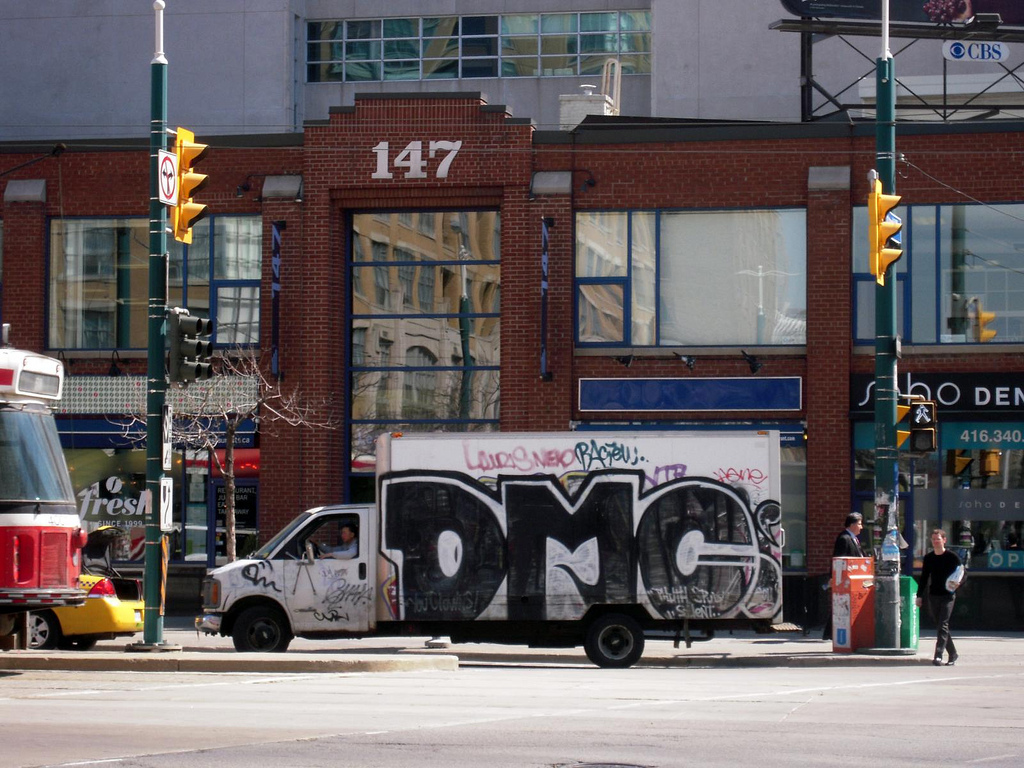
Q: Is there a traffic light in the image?
A: Yes, there is a traffic light.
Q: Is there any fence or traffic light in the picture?
A: Yes, there is a traffic light.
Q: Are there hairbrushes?
A: No, there are no hairbrushes.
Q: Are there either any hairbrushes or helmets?
A: No, there are no hairbrushes or helmets.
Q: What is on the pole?
A: The signal light is on the pole.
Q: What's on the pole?
A: The signal light is on the pole.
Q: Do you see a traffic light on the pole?
A: Yes, there is a traffic light on the pole.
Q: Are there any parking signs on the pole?
A: No, there is a traffic light on the pole.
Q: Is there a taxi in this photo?
A: Yes, there is a taxi.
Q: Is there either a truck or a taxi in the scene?
A: Yes, there is a taxi.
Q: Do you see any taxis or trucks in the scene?
A: Yes, there is a taxi.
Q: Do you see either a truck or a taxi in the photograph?
A: Yes, there is a taxi.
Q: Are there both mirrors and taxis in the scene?
A: No, there is a taxi but no mirrors.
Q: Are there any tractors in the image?
A: No, there are no tractors.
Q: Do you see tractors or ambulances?
A: No, there are no tractors or ambulances.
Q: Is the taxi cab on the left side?
A: Yes, the taxi cab is on the left of the image.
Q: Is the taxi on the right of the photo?
A: No, the taxi is on the left of the image.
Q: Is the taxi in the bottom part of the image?
A: Yes, the taxi is in the bottom of the image.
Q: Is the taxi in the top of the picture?
A: No, the taxi is in the bottom of the image.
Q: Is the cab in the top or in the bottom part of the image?
A: The cab is in the bottom of the image.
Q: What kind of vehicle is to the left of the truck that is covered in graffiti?
A: The vehicle is a taxi.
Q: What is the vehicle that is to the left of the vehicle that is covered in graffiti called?
A: The vehicle is a taxi.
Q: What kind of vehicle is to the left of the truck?
A: The vehicle is a taxi.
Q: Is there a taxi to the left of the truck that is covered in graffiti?
A: Yes, there is a taxi to the left of the truck.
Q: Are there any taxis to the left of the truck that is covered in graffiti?
A: Yes, there is a taxi to the left of the truck.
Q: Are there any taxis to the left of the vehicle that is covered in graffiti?
A: Yes, there is a taxi to the left of the truck.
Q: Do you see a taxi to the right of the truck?
A: No, the taxi is to the left of the truck.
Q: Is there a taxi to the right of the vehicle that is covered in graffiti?
A: No, the taxi is to the left of the truck.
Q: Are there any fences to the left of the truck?
A: No, there is a taxi to the left of the truck.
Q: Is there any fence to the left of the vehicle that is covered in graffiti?
A: No, there is a taxi to the left of the truck.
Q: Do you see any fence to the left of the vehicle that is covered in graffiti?
A: No, there is a taxi to the left of the truck.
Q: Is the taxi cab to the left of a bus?
A: No, the taxi cab is to the left of the truck.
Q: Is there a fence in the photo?
A: No, there are no fences.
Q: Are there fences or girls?
A: No, there are no fences or girls.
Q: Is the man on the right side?
A: Yes, the man is on the right of the image.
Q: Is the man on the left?
A: No, the man is on the right of the image.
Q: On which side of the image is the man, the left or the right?
A: The man is on the right of the image.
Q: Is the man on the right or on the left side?
A: The man is on the right of the image.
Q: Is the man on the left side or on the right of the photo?
A: The man is on the right of the image.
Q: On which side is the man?
A: The man is on the right of the image.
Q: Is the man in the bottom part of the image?
A: Yes, the man is in the bottom of the image.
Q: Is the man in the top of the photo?
A: No, the man is in the bottom of the image.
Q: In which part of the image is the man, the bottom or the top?
A: The man is in the bottom of the image.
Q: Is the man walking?
A: Yes, the man is walking.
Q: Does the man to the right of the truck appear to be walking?
A: Yes, the man is walking.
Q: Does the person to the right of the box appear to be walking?
A: Yes, the man is walking.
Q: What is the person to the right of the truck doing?
A: The man is walking.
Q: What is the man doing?
A: The man is walking.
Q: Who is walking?
A: The man is walking.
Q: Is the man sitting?
A: No, the man is walking.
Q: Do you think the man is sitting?
A: No, the man is walking.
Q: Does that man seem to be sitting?
A: No, the man is walking.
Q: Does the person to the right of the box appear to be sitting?
A: No, the man is walking.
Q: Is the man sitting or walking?
A: The man is walking.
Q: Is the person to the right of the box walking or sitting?
A: The man is walking.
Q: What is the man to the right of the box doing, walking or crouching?
A: The man is walking.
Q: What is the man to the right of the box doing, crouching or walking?
A: The man is walking.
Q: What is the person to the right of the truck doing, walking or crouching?
A: The man is walking.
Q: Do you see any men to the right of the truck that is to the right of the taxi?
A: Yes, there is a man to the right of the truck.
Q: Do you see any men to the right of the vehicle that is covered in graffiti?
A: Yes, there is a man to the right of the truck.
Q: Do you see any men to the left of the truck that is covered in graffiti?
A: No, the man is to the right of the truck.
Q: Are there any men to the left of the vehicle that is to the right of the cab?
A: No, the man is to the right of the truck.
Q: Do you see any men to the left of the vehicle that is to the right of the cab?
A: No, the man is to the right of the truck.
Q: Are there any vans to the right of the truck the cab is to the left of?
A: No, there is a man to the right of the truck.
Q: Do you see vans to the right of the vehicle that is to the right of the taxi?
A: No, there is a man to the right of the truck.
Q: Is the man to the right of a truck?
A: Yes, the man is to the right of a truck.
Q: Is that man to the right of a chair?
A: No, the man is to the right of a truck.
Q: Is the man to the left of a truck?
A: No, the man is to the right of a truck.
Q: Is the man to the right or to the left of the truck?
A: The man is to the right of the truck.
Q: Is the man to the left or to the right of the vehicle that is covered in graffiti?
A: The man is to the right of the truck.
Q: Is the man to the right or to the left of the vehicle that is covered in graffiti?
A: The man is to the right of the truck.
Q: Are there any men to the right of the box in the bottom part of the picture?
A: Yes, there is a man to the right of the box.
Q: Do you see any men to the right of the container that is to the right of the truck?
A: Yes, there is a man to the right of the box.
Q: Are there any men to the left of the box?
A: No, the man is to the right of the box.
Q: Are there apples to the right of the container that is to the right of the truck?
A: No, there is a man to the right of the box.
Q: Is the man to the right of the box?
A: Yes, the man is to the right of the box.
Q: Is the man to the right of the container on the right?
A: Yes, the man is to the right of the box.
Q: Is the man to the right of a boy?
A: No, the man is to the right of the box.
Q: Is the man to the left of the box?
A: No, the man is to the right of the box.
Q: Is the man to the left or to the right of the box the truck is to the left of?
A: The man is to the right of the box.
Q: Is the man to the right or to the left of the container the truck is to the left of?
A: The man is to the right of the box.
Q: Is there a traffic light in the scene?
A: Yes, there is a traffic light.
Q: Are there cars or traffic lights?
A: Yes, there is a traffic light.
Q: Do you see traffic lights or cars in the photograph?
A: Yes, there is a traffic light.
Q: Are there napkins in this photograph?
A: No, there are no napkins.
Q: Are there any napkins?
A: No, there are no napkins.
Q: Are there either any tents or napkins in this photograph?
A: No, there are no napkins or tents.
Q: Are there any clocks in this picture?
A: No, there are no clocks.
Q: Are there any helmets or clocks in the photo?
A: No, there are no clocks or helmets.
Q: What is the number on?
A: The number is on the building.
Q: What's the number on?
A: The number is on the building.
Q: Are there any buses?
A: No, there are no buses.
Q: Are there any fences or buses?
A: No, there are no buses or fences.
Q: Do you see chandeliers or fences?
A: No, there are no fences or chandeliers.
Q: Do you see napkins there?
A: No, there are no napkins.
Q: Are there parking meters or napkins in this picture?
A: No, there are no napkins or parking meters.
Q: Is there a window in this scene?
A: Yes, there is a window.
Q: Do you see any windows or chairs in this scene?
A: Yes, there is a window.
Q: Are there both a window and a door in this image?
A: No, there is a window but no doors.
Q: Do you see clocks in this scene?
A: No, there are no clocks.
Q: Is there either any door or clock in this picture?
A: No, there are no clocks or doors.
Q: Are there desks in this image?
A: No, there are no desks.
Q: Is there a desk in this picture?
A: No, there are no desks.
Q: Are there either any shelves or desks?
A: No, there are no desks or shelves.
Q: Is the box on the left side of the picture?
A: No, the box is on the right of the image.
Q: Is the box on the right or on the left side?
A: The box is on the right of the image.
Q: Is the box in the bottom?
A: Yes, the box is in the bottom of the image.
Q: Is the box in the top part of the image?
A: No, the box is in the bottom of the image.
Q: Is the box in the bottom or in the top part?
A: The box is in the bottom of the image.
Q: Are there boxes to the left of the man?
A: Yes, there is a box to the left of the man.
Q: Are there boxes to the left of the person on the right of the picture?
A: Yes, there is a box to the left of the man.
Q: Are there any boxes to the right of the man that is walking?
A: No, the box is to the left of the man.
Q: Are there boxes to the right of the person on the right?
A: No, the box is to the left of the man.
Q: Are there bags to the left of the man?
A: No, there is a box to the left of the man.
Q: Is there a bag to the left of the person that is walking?
A: No, there is a box to the left of the man.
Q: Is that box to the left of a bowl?
A: No, the box is to the left of the man.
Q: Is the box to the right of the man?
A: No, the box is to the left of the man.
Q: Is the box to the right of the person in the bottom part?
A: No, the box is to the left of the man.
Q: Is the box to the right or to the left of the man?
A: The box is to the left of the man.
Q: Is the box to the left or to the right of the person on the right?
A: The box is to the left of the man.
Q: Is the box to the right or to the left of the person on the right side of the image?
A: The box is to the left of the man.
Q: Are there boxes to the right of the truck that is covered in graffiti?
A: Yes, there is a box to the right of the truck.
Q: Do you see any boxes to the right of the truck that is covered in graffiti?
A: Yes, there is a box to the right of the truck.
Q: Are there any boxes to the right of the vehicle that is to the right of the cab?
A: Yes, there is a box to the right of the truck.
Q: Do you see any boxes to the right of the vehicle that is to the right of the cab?
A: Yes, there is a box to the right of the truck.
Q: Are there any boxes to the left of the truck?
A: No, the box is to the right of the truck.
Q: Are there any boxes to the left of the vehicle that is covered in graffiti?
A: No, the box is to the right of the truck.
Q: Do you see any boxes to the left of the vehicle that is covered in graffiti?
A: No, the box is to the right of the truck.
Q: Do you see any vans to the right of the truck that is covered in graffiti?
A: No, there is a box to the right of the truck.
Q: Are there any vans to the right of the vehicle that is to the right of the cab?
A: No, there is a box to the right of the truck.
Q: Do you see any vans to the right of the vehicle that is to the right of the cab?
A: No, there is a box to the right of the truck.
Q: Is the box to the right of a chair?
A: No, the box is to the right of the truck.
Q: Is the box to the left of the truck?
A: No, the box is to the right of the truck.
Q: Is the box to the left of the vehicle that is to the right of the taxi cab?
A: No, the box is to the right of the truck.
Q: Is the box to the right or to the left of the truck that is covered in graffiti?
A: The box is to the right of the truck.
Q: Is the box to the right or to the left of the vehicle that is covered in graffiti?
A: The box is to the right of the truck.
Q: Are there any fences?
A: No, there are no fences.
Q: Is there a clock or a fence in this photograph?
A: No, there are no fences or clocks.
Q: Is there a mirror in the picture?
A: No, there are no mirrors.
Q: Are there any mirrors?
A: No, there are no mirrors.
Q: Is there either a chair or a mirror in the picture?
A: No, there are no mirrors or chairs.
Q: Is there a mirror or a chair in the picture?
A: No, there are no mirrors or chairs.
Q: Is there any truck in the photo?
A: Yes, there is a truck.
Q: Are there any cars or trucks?
A: Yes, there is a truck.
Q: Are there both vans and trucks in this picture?
A: No, there is a truck but no vans.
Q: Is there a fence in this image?
A: No, there are no fences.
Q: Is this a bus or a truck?
A: This is a truck.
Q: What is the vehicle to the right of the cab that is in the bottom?
A: The vehicle is a truck.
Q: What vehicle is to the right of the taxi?
A: The vehicle is a truck.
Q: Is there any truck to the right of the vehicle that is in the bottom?
A: Yes, there is a truck to the right of the taxi.